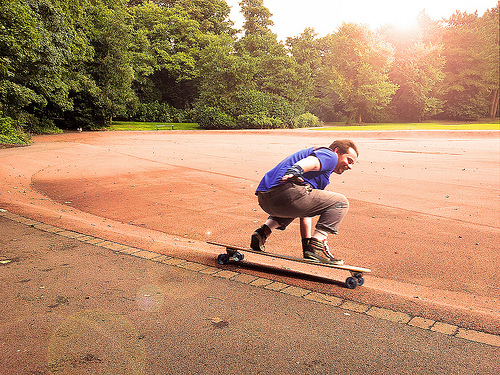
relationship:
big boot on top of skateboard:
[301, 238, 345, 267] [207, 238, 369, 293]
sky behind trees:
[226, 3, 496, 54] [154, 0, 332, 45]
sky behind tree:
[226, 3, 496, 54] [228, 3, 299, 118]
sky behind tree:
[226, 3, 496, 54] [284, 25, 327, 92]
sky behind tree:
[226, 3, 496, 54] [324, 22, 399, 122]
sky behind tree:
[226, 3, 496, 54] [417, 8, 460, 61]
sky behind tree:
[226, 3, 496, 54] [441, 4, 495, 123]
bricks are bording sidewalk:
[0, 207, 498, 347] [0, 140, 498, 374]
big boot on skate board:
[301, 238, 345, 267] [205, 237, 373, 287]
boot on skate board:
[248, 221, 271, 251] [205, 237, 373, 287]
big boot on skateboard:
[301, 238, 345, 267] [200, 233, 377, 293]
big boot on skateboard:
[297, 233, 345, 266] [200, 237, 372, 297]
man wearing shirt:
[250, 139, 358, 264] [260, 147, 352, 200]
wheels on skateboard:
[199, 243, 254, 283] [184, 217, 391, 306]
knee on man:
[323, 190, 349, 220] [259, 109, 362, 263]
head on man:
[329, 137, 356, 179] [250, 139, 358, 264]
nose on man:
[345, 160, 353, 170] [250, 139, 358, 264]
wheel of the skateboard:
[341, 276, 359, 293] [205, 236, 369, 277]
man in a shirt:
[250, 139, 358, 264] [259, 148, 337, 190]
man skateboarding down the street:
[250, 139, 358, 264] [2, 130, 497, 374]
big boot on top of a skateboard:
[301, 238, 345, 267] [199, 233, 385, 297]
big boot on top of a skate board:
[301, 238, 345, 267] [204, 239, 382, 291]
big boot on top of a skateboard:
[301, 238, 345, 267] [200, 233, 377, 293]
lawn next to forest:
[110, 122, 499, 131] [1, 0, 498, 145]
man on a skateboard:
[243, 130, 361, 275] [201, 228, 376, 295]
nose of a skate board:
[355, 266, 371, 276] [204, 236, 372, 296]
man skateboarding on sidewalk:
[250, 139, 358, 264] [0, 214, 500, 375]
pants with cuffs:
[257, 175, 355, 236] [256, 213, 341, 234]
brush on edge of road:
[128, 97, 197, 124] [9, 128, 498, 324]